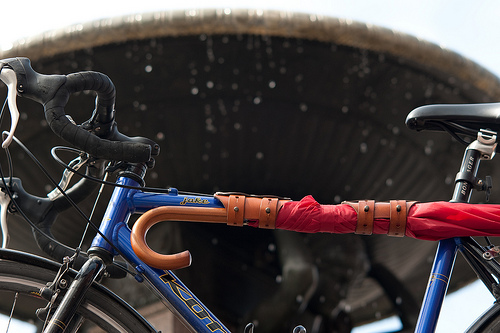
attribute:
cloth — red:
[281, 199, 498, 235]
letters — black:
[175, 193, 212, 206]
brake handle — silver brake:
[1, 63, 31, 150]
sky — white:
[2, 0, 487, 85]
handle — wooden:
[15, 65, 165, 215]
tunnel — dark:
[0, 66, 500, 331]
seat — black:
[405, 101, 497, 138]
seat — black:
[394, 70, 498, 155]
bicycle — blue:
[84, 101, 461, 301]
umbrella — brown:
[129, 193, 499, 269]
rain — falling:
[2, 30, 469, 201]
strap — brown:
[387, 200, 407, 237]